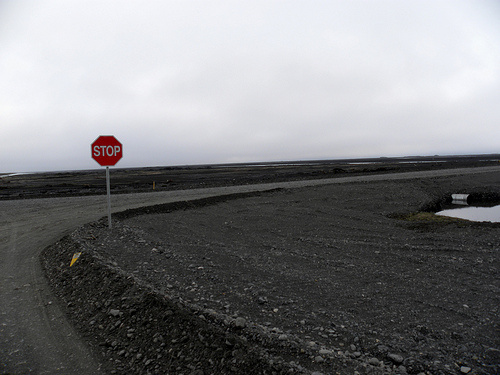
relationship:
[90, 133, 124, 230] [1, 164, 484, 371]
stop sign standing next to road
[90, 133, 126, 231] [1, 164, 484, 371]
stop sign standing on side of road